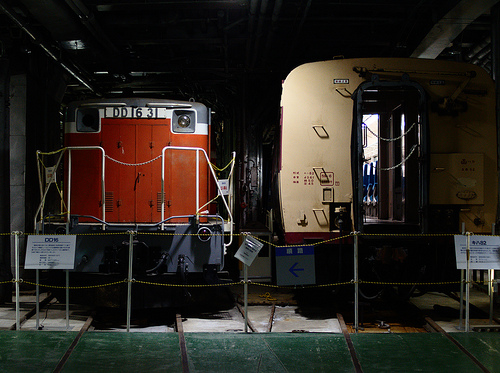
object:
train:
[43, 86, 225, 309]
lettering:
[45, 237, 59, 243]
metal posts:
[127, 231, 132, 328]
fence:
[0, 231, 499, 333]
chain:
[365, 144, 417, 171]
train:
[277, 56, 499, 302]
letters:
[113, 108, 121, 117]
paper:
[233, 235, 265, 267]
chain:
[16, 231, 129, 237]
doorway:
[357, 82, 428, 232]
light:
[177, 114, 192, 126]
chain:
[106, 154, 163, 166]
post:
[194, 149, 201, 221]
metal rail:
[352, 232, 360, 330]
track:
[52, 313, 96, 370]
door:
[357, 81, 426, 235]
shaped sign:
[24, 235, 77, 270]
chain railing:
[0, 230, 499, 331]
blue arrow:
[287, 262, 304, 277]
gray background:
[0, 0, 500, 373]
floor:
[0, 290, 500, 372]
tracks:
[253, 302, 277, 372]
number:
[135, 107, 143, 117]